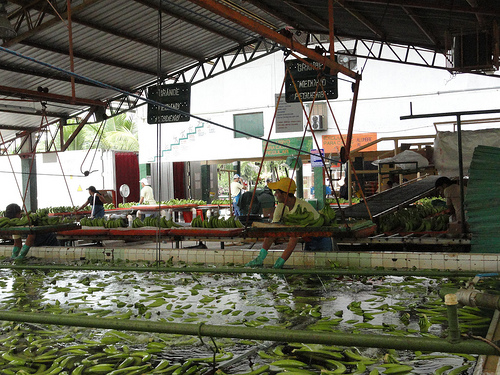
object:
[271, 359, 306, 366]
green fish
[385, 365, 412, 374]
green fish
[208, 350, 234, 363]
green fish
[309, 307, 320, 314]
green fish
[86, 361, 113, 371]
green fish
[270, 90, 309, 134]
sign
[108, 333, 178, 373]
fish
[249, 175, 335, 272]
man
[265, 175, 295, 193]
hat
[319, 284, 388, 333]
fish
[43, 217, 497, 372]
tank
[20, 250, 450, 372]
water tank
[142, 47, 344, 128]
signs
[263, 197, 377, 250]
bananas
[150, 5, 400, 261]
scale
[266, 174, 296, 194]
cap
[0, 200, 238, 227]
bananas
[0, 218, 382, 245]
tables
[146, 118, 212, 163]
line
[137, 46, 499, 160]
wall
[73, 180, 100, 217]
person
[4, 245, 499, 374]
bananas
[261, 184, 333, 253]
person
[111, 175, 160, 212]
scale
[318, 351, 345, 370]
fish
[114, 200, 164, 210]
vegetables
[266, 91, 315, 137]
wall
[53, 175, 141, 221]
background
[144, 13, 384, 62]
roof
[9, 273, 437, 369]
green fish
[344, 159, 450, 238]
conveyor belt